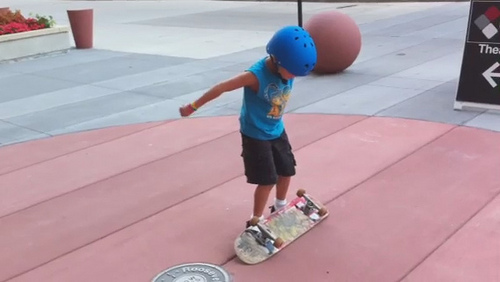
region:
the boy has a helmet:
[271, 26, 316, 73]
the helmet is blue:
[268, 29, 315, 76]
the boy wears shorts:
[236, 129, 300, 185]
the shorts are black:
[240, 121, 293, 181]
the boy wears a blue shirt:
[243, 58, 292, 136]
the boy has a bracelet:
[190, 104, 197, 107]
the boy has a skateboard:
[233, 189, 328, 268]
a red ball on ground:
[306, 12, 361, 75]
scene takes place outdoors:
[0, 3, 498, 280]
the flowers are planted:
[0, 7, 70, 50]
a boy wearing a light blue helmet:
[172, 23, 332, 264]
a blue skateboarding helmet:
[257, 21, 322, 85]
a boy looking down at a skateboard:
[185, 19, 331, 260]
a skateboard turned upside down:
[227, 176, 339, 273]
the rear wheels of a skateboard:
[294, 185, 330, 217]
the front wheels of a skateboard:
[242, 212, 284, 257]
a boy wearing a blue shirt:
[190, 16, 323, 146]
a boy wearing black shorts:
[179, 15, 329, 181]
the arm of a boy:
[161, 60, 255, 139]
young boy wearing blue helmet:
[176, 20, 321, 222]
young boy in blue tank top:
[168, 22, 323, 234]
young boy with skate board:
[176, 23, 331, 264]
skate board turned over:
[232, 188, 330, 267]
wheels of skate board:
[248, 213, 283, 248]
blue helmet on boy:
[265, 25, 318, 77]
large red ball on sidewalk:
[301, 8, 362, 75]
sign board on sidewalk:
[454, 0, 499, 115]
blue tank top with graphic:
[237, 55, 292, 142]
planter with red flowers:
[1, 5, 73, 61]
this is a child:
[180, 11, 357, 261]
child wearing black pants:
[225, 121, 316, 193]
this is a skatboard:
[220, 185, 333, 259]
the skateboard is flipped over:
[233, 172, 337, 269]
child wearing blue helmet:
[263, 14, 321, 84]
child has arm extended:
[169, 65, 260, 124]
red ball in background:
[296, 5, 386, 87]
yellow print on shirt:
[260, 76, 294, 121]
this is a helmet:
[254, 2, 321, 82]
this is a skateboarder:
[208, 94, 320, 251]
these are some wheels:
[239, 188, 289, 267]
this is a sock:
[255, 184, 302, 220]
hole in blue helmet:
[301, 40, 307, 50]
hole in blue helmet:
[292, 25, 297, 34]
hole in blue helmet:
[291, 36, 296, 46]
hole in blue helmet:
[303, 63, 308, 68]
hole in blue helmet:
[311, 63, 315, 70]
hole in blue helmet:
[298, 26, 303, 33]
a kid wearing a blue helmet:
[177, 22, 322, 234]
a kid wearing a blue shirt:
[174, 23, 321, 230]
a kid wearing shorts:
[180, 27, 322, 215]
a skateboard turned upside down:
[232, 186, 328, 264]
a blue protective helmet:
[265, 25, 322, 76]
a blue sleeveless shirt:
[238, 55, 295, 141]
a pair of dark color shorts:
[237, 130, 297, 185]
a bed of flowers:
[1, 5, 57, 35]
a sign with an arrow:
[452, 2, 498, 111]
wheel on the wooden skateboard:
[250, 213, 260, 228]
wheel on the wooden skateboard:
[272, 237, 283, 248]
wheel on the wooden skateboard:
[292, 186, 307, 202]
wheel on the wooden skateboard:
[316, 205, 327, 217]